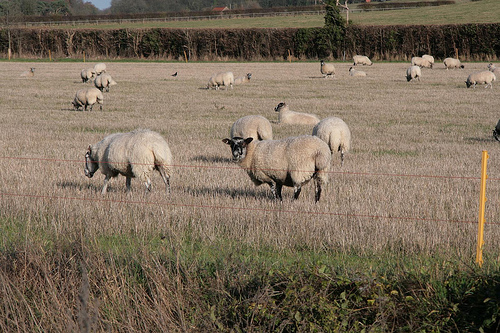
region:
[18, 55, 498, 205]
Sheep grazing in the grass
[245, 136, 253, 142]
Black ear on sheep's head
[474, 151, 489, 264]
Yellow pole in the ground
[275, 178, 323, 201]
Black legs of the sheep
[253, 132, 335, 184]
Thick wool on sheep's body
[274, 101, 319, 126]
Sheep laying in the grass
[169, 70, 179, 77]
Bird standing in the grass near sheep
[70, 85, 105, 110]
Sheep eating grass with head down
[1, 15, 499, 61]
Hedge of trees in the distance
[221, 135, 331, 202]
Sheep with gray and black face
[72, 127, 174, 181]
sheep in a field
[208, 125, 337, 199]
sheep looking at the camera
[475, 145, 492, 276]
yellow fence post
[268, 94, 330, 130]
sheep laying down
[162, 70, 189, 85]
small bird in a field of sheep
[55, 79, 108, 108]
sheep eating grass in a field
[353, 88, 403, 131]
dry grass in a feild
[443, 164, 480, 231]
wire fencing around a field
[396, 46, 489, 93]
multiple sheep in a field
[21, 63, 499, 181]
herd of sheep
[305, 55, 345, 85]
The sheep is white.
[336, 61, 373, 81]
The sheep is white.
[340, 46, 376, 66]
The sheep is white.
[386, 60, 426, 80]
The sheep is white.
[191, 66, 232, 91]
The sheep is white.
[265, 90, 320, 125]
The sheep is white.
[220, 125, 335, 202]
The sheep is white.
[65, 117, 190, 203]
The sheep is white.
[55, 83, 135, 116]
The sheep is white.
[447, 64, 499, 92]
The sheep is white.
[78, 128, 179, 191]
sheep in the field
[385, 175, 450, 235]
field's plants are dead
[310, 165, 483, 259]
this is the fencing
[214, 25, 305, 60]
trees on the other side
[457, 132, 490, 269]
pole of the fence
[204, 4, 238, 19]
house in the distance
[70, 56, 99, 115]
sheep in the field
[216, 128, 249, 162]
head of the sheep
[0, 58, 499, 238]
sheep grazing in meadow of dry grass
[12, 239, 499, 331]
greener grasses in the foreground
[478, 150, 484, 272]
a yellow fence post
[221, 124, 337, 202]
a sheep woth black face and feet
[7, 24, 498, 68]
a trimmed hedgerow in the rear of the meadow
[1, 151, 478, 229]
electrified fencing around the meadow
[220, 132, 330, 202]
only one sheep watches the photographer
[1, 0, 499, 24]
a greener meadow in the rear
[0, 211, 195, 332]
taller dried grass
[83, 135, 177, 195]
a sheep with a white face and feet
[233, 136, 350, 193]
An animal in a field.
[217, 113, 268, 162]
An animal in a field.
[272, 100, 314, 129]
An animal in a field.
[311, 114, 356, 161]
An animal in a field.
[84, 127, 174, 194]
tan sheep standing in the field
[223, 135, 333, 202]
tan sheep standing in the field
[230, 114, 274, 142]
tan sheep standing in the field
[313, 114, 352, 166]
tan sheep standing in the field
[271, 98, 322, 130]
tan sheep sleeping in the field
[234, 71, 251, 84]
tan sheep sleeping in the field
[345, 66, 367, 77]
tan sheep sleeping in the field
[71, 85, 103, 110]
tan sheep grazing in the field